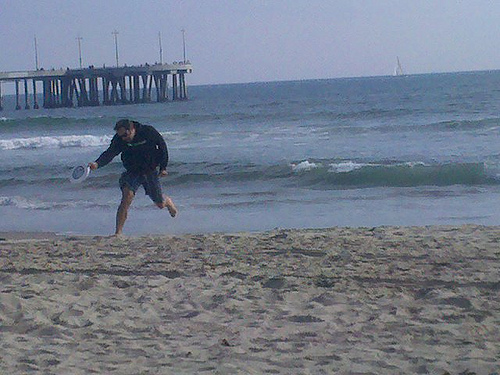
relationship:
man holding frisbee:
[88, 117, 178, 239] [70, 162, 91, 183]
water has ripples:
[3, 73, 499, 223] [287, 159, 360, 173]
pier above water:
[0, 28, 192, 111] [3, 73, 499, 223]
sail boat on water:
[392, 55, 404, 75] [3, 73, 499, 223]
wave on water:
[2, 130, 181, 152] [3, 73, 499, 223]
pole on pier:
[34, 36, 39, 72] [0, 28, 192, 111]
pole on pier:
[77, 37, 81, 70] [0, 28, 192, 111]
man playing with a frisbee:
[88, 117, 178, 239] [70, 162, 91, 183]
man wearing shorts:
[88, 117, 178, 239] [120, 167, 165, 202]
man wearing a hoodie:
[88, 117, 178, 239] [96, 121, 170, 173]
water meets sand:
[3, 73, 499, 223] [7, 226, 499, 365]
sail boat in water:
[392, 55, 404, 75] [3, 73, 499, 223]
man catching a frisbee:
[88, 117, 178, 239] [70, 162, 91, 183]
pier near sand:
[0, 28, 192, 111] [7, 226, 499, 365]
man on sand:
[88, 117, 178, 239] [7, 226, 499, 365]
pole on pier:
[181, 28, 189, 64] [0, 28, 192, 111]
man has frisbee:
[88, 117, 178, 239] [70, 162, 91, 183]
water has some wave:
[3, 73, 499, 223] [2, 130, 181, 152]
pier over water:
[0, 28, 192, 111] [3, 73, 499, 223]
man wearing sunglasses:
[88, 117, 178, 239] [118, 130, 128, 140]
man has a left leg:
[88, 117, 178, 239] [143, 171, 179, 220]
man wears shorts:
[88, 117, 178, 239] [120, 167, 165, 202]